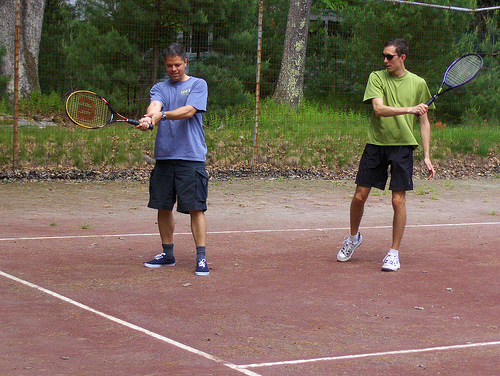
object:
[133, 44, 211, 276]
man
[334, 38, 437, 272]
man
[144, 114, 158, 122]
wrist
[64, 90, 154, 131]
tennis racket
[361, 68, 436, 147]
t-shirt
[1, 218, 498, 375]
tennis court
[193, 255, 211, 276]
tennis shoes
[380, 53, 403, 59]
sunglasses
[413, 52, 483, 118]
tennis racket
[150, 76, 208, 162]
shirt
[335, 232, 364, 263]
sneakers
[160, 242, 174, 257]
socks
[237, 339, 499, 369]
line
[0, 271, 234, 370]
line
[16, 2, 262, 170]
net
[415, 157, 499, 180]
leaves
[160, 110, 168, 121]
watch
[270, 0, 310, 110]
tree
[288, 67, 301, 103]
moss